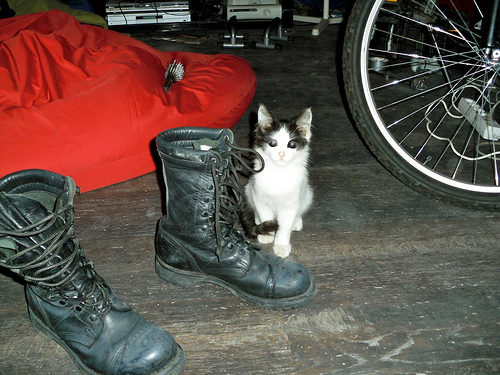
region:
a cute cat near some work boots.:
[15, 83, 425, 354]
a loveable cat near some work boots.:
[5, 90, 410, 346]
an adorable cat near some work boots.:
[46, 90, 391, 345]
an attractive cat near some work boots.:
[30, 92, 390, 353]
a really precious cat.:
[252, 96, 322, 246]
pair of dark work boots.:
[0, 171, 267, 361]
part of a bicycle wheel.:
[338, 6, 488, 209]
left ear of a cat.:
[294, 101, 322, 139]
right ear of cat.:
[253, 102, 280, 136]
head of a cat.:
[252, 98, 316, 168]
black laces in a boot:
[26, 233, 84, 273]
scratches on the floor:
[281, 309, 393, 351]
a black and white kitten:
[254, 106, 311, 261]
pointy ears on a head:
[255, 93, 310, 130]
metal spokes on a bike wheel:
[388, 54, 443, 141]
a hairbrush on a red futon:
[158, 47, 194, 91]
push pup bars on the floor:
[216, 13, 293, 60]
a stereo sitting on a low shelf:
[110, 3, 197, 27]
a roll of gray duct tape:
[367, 51, 388, 71]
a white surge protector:
[450, 97, 497, 149]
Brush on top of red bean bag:
[1, 10, 253, 196]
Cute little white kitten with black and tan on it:
[243, 98, 316, 260]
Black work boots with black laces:
[0, 125, 318, 374]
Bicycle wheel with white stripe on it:
[339, 2, 498, 212]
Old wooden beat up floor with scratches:
[3, 32, 498, 374]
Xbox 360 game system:
[225, 3, 282, 23]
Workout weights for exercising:
[218, 19, 287, 54]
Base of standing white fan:
[291, 1, 344, 41]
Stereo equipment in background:
[105, 0, 191, 25]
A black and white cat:
[251, 102, 333, 259]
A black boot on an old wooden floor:
[156, 130, 318, 310]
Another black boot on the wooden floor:
[1, 168, 188, 373]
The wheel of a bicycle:
[343, 3, 498, 217]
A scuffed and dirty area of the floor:
[203, 302, 455, 374]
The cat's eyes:
[264, 133, 308, 154]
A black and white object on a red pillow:
[161, 52, 196, 99]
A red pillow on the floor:
[1, 10, 259, 192]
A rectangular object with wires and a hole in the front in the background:
[101, 0, 206, 29]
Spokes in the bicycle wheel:
[371, 48, 431, 131]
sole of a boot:
[260, 299, 293, 318]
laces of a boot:
[215, 175, 242, 233]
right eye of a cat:
[268, 139, 278, 148]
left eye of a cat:
[287, 139, 295, 151]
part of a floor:
[386, 252, 438, 309]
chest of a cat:
[259, 173, 284, 192]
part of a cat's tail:
[242, 221, 277, 235]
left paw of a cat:
[273, 241, 289, 256]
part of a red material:
[10, 45, 67, 87]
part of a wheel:
[324, 28, 423, 174]